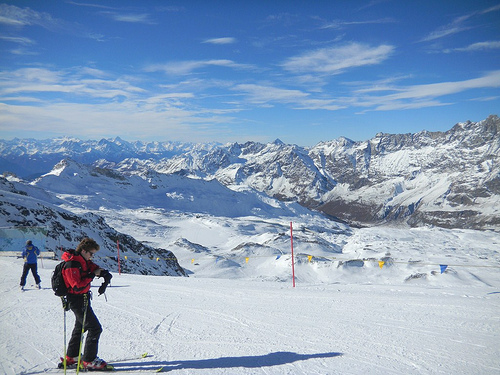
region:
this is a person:
[53, 221, 138, 368]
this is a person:
[6, 232, 63, 292]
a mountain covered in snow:
[220, 133, 342, 227]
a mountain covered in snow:
[48, 143, 170, 226]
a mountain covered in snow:
[1, 186, 161, 312]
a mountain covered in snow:
[265, 127, 339, 212]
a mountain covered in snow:
[372, 133, 484, 243]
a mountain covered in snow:
[324, 220, 433, 313]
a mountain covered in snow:
[159, 126, 290, 199]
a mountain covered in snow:
[95, 200, 192, 304]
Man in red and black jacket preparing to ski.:
[50, 235, 117, 373]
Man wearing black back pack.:
[48, 237, 115, 374]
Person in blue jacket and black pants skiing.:
[0, 112, 498, 293]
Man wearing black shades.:
[48, 232, 130, 374]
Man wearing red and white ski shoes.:
[46, 234, 119, 374]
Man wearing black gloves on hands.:
[50, 229, 127, 374]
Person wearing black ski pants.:
[8, 238, 48, 294]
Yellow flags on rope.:
[114, 251, 496, 268]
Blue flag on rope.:
[109, 258, 496, 278]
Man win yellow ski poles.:
[43, 234, 119, 374]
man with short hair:
[78, 234, 103, 261]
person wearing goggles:
[67, 224, 109, 255]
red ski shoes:
[51, 347, 121, 372]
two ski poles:
[56, 298, 91, 371]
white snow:
[186, 289, 264, 346]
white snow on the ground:
[176, 284, 480, 356]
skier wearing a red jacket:
[44, 224, 119, 309]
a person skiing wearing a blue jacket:
[8, 233, 44, 294]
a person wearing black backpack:
[45, 233, 118, 306]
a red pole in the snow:
[279, 213, 309, 297]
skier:
[41, 243, 127, 366]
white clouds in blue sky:
[94, 45, 150, 84]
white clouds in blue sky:
[368, 46, 404, 109]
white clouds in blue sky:
[223, 26, 265, 61]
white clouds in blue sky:
[436, 47, 473, 103]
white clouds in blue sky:
[27, 23, 71, 86]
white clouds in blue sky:
[116, 28, 178, 96]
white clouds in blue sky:
[227, 61, 288, 97]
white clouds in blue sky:
[268, 29, 337, 112]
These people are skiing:
[10, 233, 140, 359]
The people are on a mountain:
[7, 224, 171, 351]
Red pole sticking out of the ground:
[277, 218, 319, 302]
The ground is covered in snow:
[177, 295, 491, 373]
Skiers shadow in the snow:
[129, 342, 355, 372]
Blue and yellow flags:
[121, 246, 471, 270]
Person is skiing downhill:
[15, 226, 47, 302]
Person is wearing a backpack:
[46, 255, 102, 307]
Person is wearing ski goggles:
[78, 236, 113, 267]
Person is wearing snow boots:
[61, 351, 112, 371]